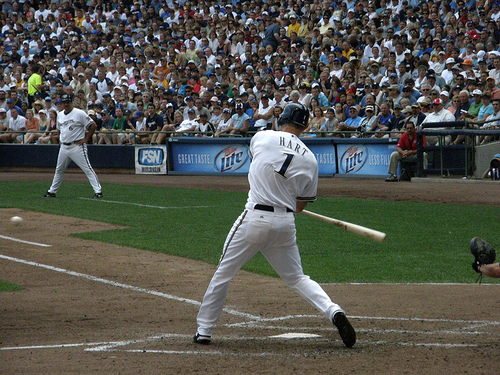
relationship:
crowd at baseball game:
[2, 1, 499, 143] [5, 69, 497, 372]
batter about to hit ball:
[194, 102, 357, 349] [9, 214, 23, 226]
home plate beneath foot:
[271, 333, 320, 338] [330, 308, 357, 349]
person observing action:
[44, 95, 105, 201] [144, 77, 424, 357]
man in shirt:
[367, 98, 440, 187] [395, 131, 425, 151]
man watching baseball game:
[367, 98, 440, 187] [0, 139, 498, 375]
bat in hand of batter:
[299, 206, 385, 241] [192, 102, 357, 349]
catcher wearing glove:
[472, 234, 497, 277] [469, 236, 495, 270]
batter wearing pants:
[192, 102, 357, 349] [195, 202, 345, 334]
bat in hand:
[298, 209, 387, 242] [296, 198, 303, 210]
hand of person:
[296, 198, 303, 210] [192, 101, 357, 348]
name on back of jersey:
[278, 133, 310, 157] [247, 128, 319, 212]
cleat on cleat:
[189, 323, 213, 339] [193, 332, 214, 344]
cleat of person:
[193, 332, 214, 344] [192, 101, 357, 348]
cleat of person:
[334, 309, 357, 351] [192, 101, 357, 348]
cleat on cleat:
[334, 309, 357, 351] [334, 309, 357, 351]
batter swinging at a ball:
[192, 102, 357, 349] [199, 105, 392, 347]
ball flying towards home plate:
[10, 216, 23, 226] [270, 325, 321, 337]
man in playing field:
[385, 121, 432, 183] [4, 166, 479, 356]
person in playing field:
[191, 100, 357, 349] [4, 166, 479, 356]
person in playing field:
[44, 91, 104, 201] [4, 166, 479, 356]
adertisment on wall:
[163, 140, 402, 178] [0, 140, 415, 179]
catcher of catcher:
[469, 236, 498, 264] [466, 235, 498, 286]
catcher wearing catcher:
[469, 236, 498, 264] [469, 236, 498, 264]